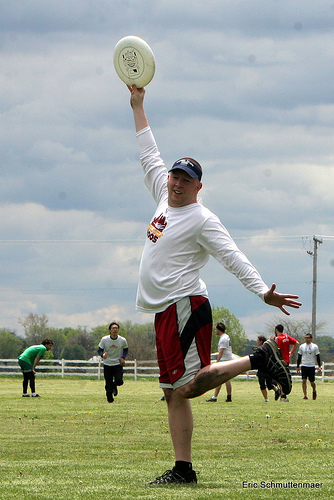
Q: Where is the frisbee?
A: Man's right hand.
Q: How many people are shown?
A: 7.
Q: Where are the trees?
A: Outside the fence.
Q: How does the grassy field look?
A: Mowed.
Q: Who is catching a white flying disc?
A: A man.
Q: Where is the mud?
A: On left leg.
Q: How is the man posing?
A: With frisbee.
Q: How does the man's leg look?
A: Bent.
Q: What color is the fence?
A: White.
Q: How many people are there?
A: 7.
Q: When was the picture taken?
A: During the day.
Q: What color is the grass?
A: Green.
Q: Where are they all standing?
A: On the grass.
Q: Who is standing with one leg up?
A: The man in the forefront.